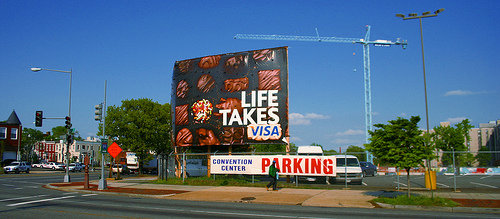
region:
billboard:
[172, 43, 284, 140]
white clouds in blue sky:
[314, 76, 342, 108]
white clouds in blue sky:
[458, 41, 482, 72]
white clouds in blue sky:
[420, 76, 458, 91]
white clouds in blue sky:
[65, 29, 119, 64]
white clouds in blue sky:
[130, 16, 154, 56]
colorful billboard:
[155, 48, 307, 156]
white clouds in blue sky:
[81, 35, 126, 82]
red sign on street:
[95, 136, 127, 163]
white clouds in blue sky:
[472, 25, 497, 57]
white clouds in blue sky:
[94, 23, 149, 64]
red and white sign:
[195, 151, 349, 183]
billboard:
[157, 43, 301, 161]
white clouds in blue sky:
[7, 11, 79, 51]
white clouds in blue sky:
[87, 5, 119, 30]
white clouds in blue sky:
[97, 66, 135, 90]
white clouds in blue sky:
[337, 19, 377, 63]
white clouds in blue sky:
[451, 11, 481, 59]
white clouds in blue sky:
[302, 72, 336, 99]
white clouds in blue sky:
[85, 32, 122, 64]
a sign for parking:
[208, 153, 335, 177]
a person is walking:
[263, 159, 280, 190]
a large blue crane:
[230, 27, 410, 164]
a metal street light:
[32, 66, 72, 183]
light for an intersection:
[35, 110, 42, 126]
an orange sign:
[106, 139, 121, 159]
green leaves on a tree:
[103, 94, 172, 151]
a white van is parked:
[330, 150, 365, 183]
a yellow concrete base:
[422, 163, 435, 185]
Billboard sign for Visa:
[166, 43, 295, 150]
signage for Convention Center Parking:
[202, 150, 354, 177]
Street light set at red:
[26, 103, 83, 190]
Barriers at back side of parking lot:
[393, 150, 498, 177]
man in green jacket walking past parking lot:
[262, 155, 286, 200]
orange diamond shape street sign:
[102, 136, 126, 187]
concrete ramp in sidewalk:
[160, 185, 317, 206]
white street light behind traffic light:
[22, 58, 90, 195]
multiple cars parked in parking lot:
[160, 143, 389, 190]